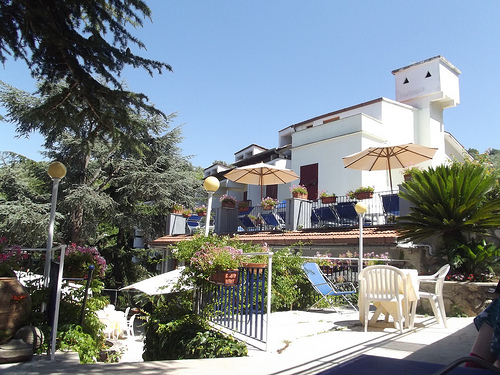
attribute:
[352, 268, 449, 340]
chairs — white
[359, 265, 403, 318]
chair — white, plastic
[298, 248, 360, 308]
chair — blue, lounging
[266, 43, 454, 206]
building — tall, white, large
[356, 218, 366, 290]
post — white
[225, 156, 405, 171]
umbrellas — shade, white, tan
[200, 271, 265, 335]
bars — dark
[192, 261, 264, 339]
fence — little, black, metal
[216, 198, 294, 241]
chairs — blue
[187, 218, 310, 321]
plants — green, growing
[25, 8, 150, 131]
tree — tall, green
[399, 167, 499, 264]
tree — palm, small, little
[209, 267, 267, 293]
box — planter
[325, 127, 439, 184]
umbrella — white, beige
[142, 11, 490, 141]
sky — blue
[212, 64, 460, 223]
house — white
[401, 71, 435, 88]
shapes — triangle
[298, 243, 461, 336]
furniture — lawn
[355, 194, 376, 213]
globes — round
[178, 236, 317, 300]
shrubbery — green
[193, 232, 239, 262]
flowers — pink, planted, purple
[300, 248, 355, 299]
frame — metal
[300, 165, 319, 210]
door — burgundy, brown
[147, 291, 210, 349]
shrub — large, green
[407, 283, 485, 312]
wall — stone, decorative